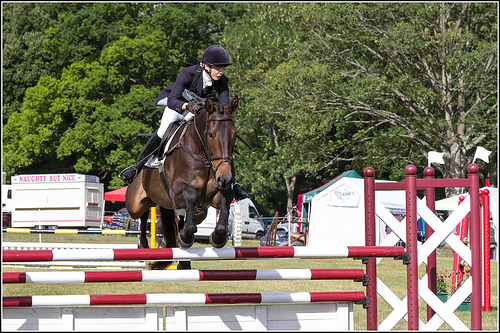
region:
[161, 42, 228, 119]
person wearing black hat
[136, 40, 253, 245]
person riding a horse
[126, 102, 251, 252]
brown horse jumping over fence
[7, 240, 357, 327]
red and white fence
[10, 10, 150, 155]
trees with green leaves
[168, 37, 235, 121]
person wearing a black jacket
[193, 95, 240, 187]
horse wearing a harness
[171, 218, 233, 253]
hooves of a horse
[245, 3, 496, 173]
green trees in the background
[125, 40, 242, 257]
person and a horse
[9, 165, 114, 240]
white closed snack bar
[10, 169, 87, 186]
white sign with red lettering saying naughty but nice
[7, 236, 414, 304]
red and white bars of horse jump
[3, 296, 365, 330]
white base of horse jump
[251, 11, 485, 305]
trees located behind horse jumping arena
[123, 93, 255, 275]
brown muscular quarter horse jumping obstacle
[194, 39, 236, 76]
black safety horse riding helmet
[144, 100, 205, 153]
white horse riding pants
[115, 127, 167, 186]
black leather riding boots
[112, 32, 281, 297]
woman riding horse that is completing jumping course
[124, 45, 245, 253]
a woman and a horse riding together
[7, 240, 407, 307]
the poles the horse is jumping over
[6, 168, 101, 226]
a kiosk stting in the parking lot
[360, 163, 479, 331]
a scoffolding holding the poles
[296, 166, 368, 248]
some tents in the parking lot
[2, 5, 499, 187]
some green leafy trees in the background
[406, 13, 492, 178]
the trunk and some branches on the tree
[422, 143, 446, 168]
a little white flag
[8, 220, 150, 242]
a black and yellow pole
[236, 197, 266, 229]
a van parked in the parking lot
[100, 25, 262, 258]
a horse rider in a brown horse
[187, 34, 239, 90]
a black hat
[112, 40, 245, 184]
a rider wears black and white cloths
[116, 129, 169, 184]
black boot on leg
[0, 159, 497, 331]
an obstacle of equestrian race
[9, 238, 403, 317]
poles are red and white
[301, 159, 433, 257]
a tent color white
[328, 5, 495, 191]
trunk of a tree with branches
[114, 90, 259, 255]
horse is jumping an obstacle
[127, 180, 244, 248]
legs of horse are bend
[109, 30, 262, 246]
the horse is jumping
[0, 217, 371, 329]
the bars are red and white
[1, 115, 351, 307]
the horse is jumping over the bars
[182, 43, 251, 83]
the girl is wearing a hat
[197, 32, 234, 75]
the hat is black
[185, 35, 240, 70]
this is a riding hat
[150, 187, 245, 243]
the legs are black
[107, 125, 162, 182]
the woman is wearing riding boots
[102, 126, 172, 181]
the boots are black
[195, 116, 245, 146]
the eyes are open